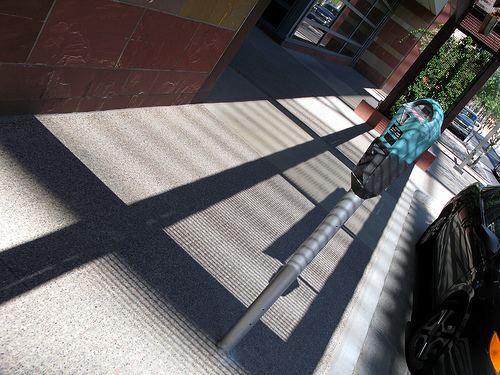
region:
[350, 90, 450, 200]
a parking meter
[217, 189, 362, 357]
the pole supporting a parking meter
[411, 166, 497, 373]
a black car parked on the side of the road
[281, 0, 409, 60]
a glass window in the front of a building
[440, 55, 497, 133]
a support column in a buiding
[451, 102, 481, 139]
a blue truck parked alongisde the road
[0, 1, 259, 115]
a large square tile covered wall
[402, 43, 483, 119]
a tree beyond the covered area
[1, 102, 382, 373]
a sidewalk in front of a building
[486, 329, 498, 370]
a light on the front of a car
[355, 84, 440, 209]
The blue and black parking meter.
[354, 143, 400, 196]
The black portion of the parking meter.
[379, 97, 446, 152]
The blue portion of the parking meter.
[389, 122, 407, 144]
The two black stickers on the blue portion of the parking meter.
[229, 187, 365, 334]
The gray pole the parking meter is mounted on.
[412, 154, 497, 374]
The black vehicle to the right of the parking meter.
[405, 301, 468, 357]
The front tire of the black vehicle.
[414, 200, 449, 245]
The back tire of the black vehicle.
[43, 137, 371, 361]
The sidewalk the parking meter is located.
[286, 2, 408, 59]
The windows on the building to the left.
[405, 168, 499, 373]
a car partly captured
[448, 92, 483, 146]
a blue car in the background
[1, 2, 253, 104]
the wall is made of stone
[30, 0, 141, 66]
the wall is made of stone is brown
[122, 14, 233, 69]
the wall is made of stone is brown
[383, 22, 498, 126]
this is a house plant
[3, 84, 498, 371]
the floor is white and black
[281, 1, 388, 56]
this is a glass partition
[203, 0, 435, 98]
this is the entrance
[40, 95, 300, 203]
the floor is white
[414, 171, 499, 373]
Black car parked on street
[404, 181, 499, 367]
Black car next to side walk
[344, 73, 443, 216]
meter is blue and black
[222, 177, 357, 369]
Silver metal pole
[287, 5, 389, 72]
Windows on building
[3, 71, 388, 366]
Sidewalk made of concrete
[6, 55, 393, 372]
Sidewalk is gray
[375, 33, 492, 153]
Green plants in front of building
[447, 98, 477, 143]
Blue truck is parked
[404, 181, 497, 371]
Black car is shiny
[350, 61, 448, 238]
Blue and gray parking meter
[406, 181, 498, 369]
Shiny black car parked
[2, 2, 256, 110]
Bricks are red and yellow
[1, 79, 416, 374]
Gray paved sidewalk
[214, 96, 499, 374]
Black car next to parking meter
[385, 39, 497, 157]
Trees in the distance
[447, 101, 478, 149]
Blue truck coming up street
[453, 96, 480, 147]
Truck is blue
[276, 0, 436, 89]
Windows on brick building